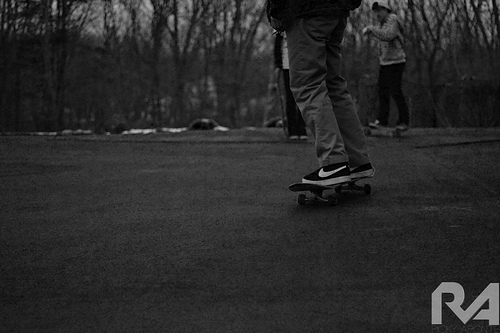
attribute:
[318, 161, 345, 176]
check — white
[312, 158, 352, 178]
swoosh — white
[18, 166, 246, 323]
ground — black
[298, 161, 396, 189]
shoes — white, black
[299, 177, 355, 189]
bottom — white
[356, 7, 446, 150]
kid — in the picture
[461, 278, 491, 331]
letter — in the picture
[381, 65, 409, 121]
pants — dark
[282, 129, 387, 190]
sneakers — white, black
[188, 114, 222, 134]
car — parked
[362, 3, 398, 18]
hat — white